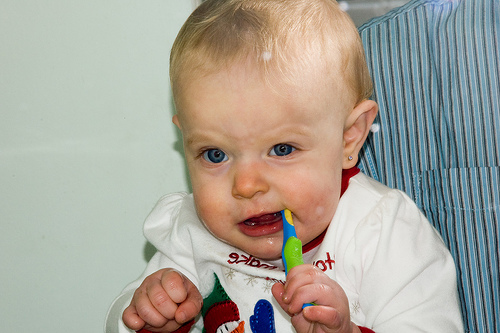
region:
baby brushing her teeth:
[162, 29, 379, 331]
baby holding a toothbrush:
[224, 180, 318, 327]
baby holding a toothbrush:
[178, 59, 345, 322]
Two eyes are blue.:
[196, 142, 298, 166]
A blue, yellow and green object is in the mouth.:
[245, 210, 309, 269]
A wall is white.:
[1, 0, 416, 331]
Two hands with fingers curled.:
[123, 266, 360, 331]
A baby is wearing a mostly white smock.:
[122, 170, 460, 332]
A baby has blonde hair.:
[171, 0, 379, 263]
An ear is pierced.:
[341, 100, 379, 169]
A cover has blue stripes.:
[355, 0, 499, 331]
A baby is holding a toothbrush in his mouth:
[3, 0, 497, 328]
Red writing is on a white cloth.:
[226, 250, 342, 277]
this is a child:
[96, 0, 486, 330]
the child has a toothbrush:
[274, 198, 320, 311]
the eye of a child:
[266, 126, 304, 168]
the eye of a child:
[186, 137, 238, 183]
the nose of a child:
[229, 180, 270, 204]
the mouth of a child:
[229, 209, 302, 251]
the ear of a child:
[330, 99, 390, 183]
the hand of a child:
[276, 263, 395, 330]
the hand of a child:
[277, 271, 368, 331]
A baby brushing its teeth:
[82, 3, 435, 326]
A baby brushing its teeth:
[105, 5, 416, 330]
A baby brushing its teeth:
[91, 2, 436, 327]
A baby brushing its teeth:
[105, 1, 420, 327]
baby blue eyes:
[191, 137, 306, 167]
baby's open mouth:
[232, 207, 291, 240]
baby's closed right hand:
[116, 264, 205, 331]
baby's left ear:
[335, 97, 382, 175]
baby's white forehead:
[168, 72, 342, 131]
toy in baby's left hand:
[275, 203, 354, 330]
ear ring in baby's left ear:
[341, 149, 361, 168]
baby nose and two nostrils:
[228, 158, 272, 205]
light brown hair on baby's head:
[164, 6, 369, 98]